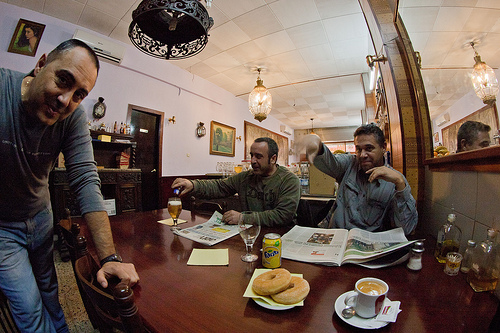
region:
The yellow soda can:
[260, 233, 281, 270]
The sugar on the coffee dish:
[382, 298, 399, 325]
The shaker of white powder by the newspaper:
[406, 235, 426, 275]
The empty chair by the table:
[60, 233, 150, 331]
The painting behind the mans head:
[12, 8, 42, 66]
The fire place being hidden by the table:
[42, 165, 143, 272]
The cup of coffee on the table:
[325, 279, 406, 329]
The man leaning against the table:
[6, 22, 126, 332]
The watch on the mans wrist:
[96, 253, 126, 268]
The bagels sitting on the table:
[246, 263, 318, 314]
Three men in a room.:
[4, 35, 421, 320]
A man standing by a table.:
[2, 31, 142, 327]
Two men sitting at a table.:
[172, 123, 422, 235]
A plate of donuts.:
[241, 265, 309, 311]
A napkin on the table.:
[184, 244, 231, 269]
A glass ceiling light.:
[241, 60, 278, 122]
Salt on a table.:
[407, 239, 425, 271]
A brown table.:
[50, 201, 485, 331]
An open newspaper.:
[273, 221, 413, 270]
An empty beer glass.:
[236, 209, 264, 265]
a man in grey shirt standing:
[1, 39, 138, 331]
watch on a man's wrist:
[98, 251, 120, 269]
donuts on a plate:
[249, 266, 310, 308]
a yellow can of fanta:
[261, 233, 283, 268]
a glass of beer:
[166, 196, 184, 229]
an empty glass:
[239, 209, 260, 263]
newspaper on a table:
[274, 222, 420, 269]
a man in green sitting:
[174, 139, 297, 224]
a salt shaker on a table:
[406, 239, 423, 269]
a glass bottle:
[437, 202, 462, 269]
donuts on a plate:
[227, 260, 324, 309]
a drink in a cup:
[325, 275, 430, 330]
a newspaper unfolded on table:
[282, 211, 424, 280]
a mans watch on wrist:
[83, 241, 145, 292]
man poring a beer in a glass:
[159, 170, 199, 251]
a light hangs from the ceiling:
[231, 60, 305, 134]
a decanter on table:
[434, 193, 499, 267]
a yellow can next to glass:
[236, 203, 288, 272]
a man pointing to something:
[286, 120, 360, 189]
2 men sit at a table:
[152, 123, 483, 245]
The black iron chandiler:
[126, 1, 220, 65]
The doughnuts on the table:
[253, 263, 311, 314]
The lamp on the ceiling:
[243, 62, 280, 129]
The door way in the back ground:
[123, 113, 165, 197]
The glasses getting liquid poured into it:
[167, 183, 189, 230]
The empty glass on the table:
[227, 198, 255, 265]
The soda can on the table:
[262, 228, 284, 268]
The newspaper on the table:
[279, 222, 413, 267]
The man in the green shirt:
[165, 139, 297, 236]